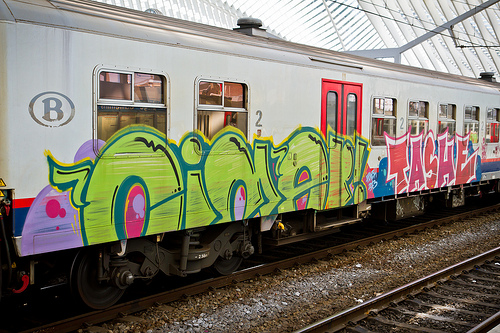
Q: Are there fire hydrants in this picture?
A: No, there are no fire hydrants.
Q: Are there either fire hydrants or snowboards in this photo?
A: No, there are no fire hydrants or snowboards.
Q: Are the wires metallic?
A: Yes, the wires are metallic.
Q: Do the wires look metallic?
A: Yes, the wires are metallic.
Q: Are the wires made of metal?
A: Yes, the wires are made of metal.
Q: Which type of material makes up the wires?
A: The wires are made of metal.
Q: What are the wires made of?
A: The wires are made of metal.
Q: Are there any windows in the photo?
A: Yes, there is a window.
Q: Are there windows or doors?
A: Yes, there is a window.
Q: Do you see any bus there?
A: No, there are no buses.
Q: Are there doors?
A: Yes, there is a door.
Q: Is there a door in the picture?
A: Yes, there is a door.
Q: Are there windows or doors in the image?
A: Yes, there is a door.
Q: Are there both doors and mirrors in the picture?
A: No, there is a door but no mirrors.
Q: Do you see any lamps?
A: No, there are no lamps.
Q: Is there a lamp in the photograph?
A: No, there are no lamps.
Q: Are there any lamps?
A: No, there are no lamps.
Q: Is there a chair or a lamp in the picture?
A: No, there are no lamps or chairs.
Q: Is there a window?
A: Yes, there is a window.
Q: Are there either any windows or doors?
A: Yes, there is a window.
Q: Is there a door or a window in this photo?
A: Yes, there is a window.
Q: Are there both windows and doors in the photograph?
A: Yes, there are both a window and a door.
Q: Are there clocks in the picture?
A: No, there are no clocks.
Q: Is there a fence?
A: No, there are no fences.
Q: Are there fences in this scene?
A: No, there are no fences.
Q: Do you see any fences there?
A: No, there are no fences.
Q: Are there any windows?
A: Yes, there is a window.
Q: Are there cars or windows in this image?
A: Yes, there is a window.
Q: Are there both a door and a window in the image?
A: Yes, there are both a window and a door.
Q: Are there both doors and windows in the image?
A: Yes, there are both a window and a door.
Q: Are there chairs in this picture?
A: No, there are no chairs.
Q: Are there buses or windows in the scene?
A: Yes, there is a window.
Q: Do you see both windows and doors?
A: Yes, there are both a window and a door.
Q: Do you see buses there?
A: No, there are no buses.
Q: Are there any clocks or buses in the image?
A: No, there are no buses or clocks.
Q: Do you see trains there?
A: Yes, there is a train.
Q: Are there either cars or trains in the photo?
A: Yes, there is a train.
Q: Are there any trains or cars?
A: Yes, there is a train.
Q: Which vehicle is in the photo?
A: The vehicle is a train.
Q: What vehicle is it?
A: The vehicle is a train.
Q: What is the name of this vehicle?
A: That is a train.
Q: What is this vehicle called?
A: That is a train.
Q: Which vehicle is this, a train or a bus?
A: That is a train.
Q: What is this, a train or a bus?
A: This is a train.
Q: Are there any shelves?
A: No, there are no shelves.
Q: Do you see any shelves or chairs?
A: No, there are no shelves or chairs.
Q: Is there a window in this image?
A: Yes, there is a window.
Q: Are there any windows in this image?
A: Yes, there is a window.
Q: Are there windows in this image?
A: Yes, there is a window.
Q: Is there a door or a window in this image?
A: Yes, there is a window.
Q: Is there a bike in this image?
A: No, there are no bikes.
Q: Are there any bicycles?
A: No, there are no bicycles.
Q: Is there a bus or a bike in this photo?
A: No, there are no bikes or buses.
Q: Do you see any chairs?
A: No, there are no chairs.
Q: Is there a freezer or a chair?
A: No, there are no chairs or refrigerators.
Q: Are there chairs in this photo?
A: No, there are no chairs.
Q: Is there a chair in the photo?
A: No, there are no chairs.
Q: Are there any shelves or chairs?
A: No, there are no chairs or shelves.